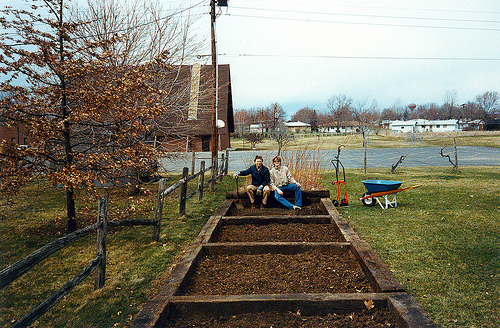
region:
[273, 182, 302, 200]
the pants are blue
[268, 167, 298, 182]
the shirt is brown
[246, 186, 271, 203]
the pants are brown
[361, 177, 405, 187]
the wheel borrow is blue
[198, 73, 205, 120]
the roof is brown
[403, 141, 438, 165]
the court is tarmaced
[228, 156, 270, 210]
woamn is holding spade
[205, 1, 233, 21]
transformer is on the elecrical post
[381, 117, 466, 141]
house are in the back ground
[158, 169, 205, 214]
the fence is wooden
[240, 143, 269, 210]
this is a person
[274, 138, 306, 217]
this is a person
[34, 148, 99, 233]
a branch with dry leaves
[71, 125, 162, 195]
a branch with dry leaves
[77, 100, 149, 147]
a branch with dry leaves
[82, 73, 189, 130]
a branch with dry leaves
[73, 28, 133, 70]
a branch with dry leaves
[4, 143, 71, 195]
a branch with dry leaves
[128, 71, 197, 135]
a branch with dry leaves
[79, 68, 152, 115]
a branch with dry leaves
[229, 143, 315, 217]
two people sitting on the ground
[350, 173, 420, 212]
wheel barrow on the grass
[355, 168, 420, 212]
blue, orange, and white wheel barrow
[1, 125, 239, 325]
wooden fence along the grass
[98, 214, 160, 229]
wooden post falling down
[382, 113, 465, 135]
white building in the distance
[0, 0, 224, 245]
orange leaves on the tree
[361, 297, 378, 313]
leaf in the dirt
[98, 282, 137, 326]
small leave on the ground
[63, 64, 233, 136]
the roof is brown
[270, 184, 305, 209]
the pants are blue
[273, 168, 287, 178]
the shirt is brown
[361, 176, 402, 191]
the wheel borrow is blue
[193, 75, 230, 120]
the roof is brown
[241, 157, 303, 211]
the people are sitted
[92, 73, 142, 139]
the leaves are brown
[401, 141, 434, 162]
the court is grey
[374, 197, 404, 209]
the whell borrow legs are white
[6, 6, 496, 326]
the season is autumn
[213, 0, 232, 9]
transformer is on the post